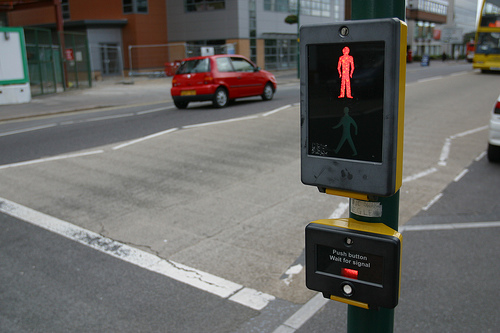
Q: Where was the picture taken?
A: It was taken at the pavement.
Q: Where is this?
A: This is at the pavement.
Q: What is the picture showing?
A: It is showing a pavement.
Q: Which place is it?
A: It is a pavement.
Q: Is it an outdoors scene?
A: Yes, it is outdoors.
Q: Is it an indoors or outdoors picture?
A: It is outdoors.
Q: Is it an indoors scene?
A: No, it is outdoors.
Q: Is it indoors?
A: No, it is outdoors.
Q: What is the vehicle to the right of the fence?
A: The vehicle is a car.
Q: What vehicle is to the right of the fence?
A: The vehicle is a car.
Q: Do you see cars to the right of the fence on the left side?
A: Yes, there is a car to the right of the fence.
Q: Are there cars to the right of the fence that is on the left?
A: Yes, there is a car to the right of the fence.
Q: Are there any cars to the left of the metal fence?
A: No, the car is to the right of the fence.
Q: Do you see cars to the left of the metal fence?
A: No, the car is to the right of the fence.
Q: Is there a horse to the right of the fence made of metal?
A: No, there is a car to the right of the fence.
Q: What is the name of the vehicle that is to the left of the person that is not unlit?
A: The vehicle is a car.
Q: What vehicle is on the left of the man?
A: The vehicle is a car.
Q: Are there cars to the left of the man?
A: Yes, there is a car to the left of the man.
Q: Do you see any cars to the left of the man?
A: Yes, there is a car to the left of the man.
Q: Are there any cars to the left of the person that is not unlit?
A: Yes, there is a car to the left of the man.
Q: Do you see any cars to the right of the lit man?
A: No, the car is to the left of the man.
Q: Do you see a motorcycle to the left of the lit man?
A: No, there is a car to the left of the man.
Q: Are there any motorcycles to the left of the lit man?
A: No, there is a car to the left of the man.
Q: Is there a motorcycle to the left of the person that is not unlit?
A: No, there is a car to the left of the man.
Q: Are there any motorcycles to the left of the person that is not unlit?
A: No, there is a car to the left of the man.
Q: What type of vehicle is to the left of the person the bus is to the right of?
A: The vehicle is a car.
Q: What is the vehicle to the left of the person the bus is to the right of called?
A: The vehicle is a car.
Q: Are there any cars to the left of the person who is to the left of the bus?
A: Yes, there is a car to the left of the person.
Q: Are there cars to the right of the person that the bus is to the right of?
A: No, the car is to the left of the person.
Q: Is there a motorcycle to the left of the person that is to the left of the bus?
A: No, there is a car to the left of the person.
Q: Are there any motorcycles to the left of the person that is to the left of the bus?
A: No, there is a car to the left of the person.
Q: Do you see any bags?
A: No, there are no bags.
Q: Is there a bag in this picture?
A: No, there are no bags.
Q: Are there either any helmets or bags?
A: No, there are no bags or helmets.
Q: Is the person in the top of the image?
A: Yes, the person is in the top of the image.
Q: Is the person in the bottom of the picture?
A: No, the person is in the top of the image.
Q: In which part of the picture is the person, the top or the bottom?
A: The person is in the top of the image.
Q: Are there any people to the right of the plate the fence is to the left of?
A: Yes, there is a person to the right of the plate.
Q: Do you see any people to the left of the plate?
A: No, the person is to the right of the plate.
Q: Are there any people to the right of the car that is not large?
A: Yes, there is a person to the right of the car.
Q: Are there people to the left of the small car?
A: No, the person is to the right of the car.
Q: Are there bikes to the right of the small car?
A: No, there is a person to the right of the car.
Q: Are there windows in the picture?
A: Yes, there are windows.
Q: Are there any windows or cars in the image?
A: Yes, there are windows.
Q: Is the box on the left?
A: No, the box is on the right of the image.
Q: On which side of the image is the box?
A: The box is on the right of the image.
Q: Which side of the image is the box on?
A: The box is on the right of the image.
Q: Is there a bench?
A: No, there are no benches.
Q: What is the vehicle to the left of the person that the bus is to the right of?
A: The vehicle is a car.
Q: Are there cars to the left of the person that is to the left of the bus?
A: Yes, there is a car to the left of the person.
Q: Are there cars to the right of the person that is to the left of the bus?
A: No, the car is to the left of the person.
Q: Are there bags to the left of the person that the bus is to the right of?
A: No, there is a car to the left of the person.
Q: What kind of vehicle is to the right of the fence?
A: The vehicle is a car.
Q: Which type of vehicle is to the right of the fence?
A: The vehicle is a car.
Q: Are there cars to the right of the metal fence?
A: Yes, there is a car to the right of the fence.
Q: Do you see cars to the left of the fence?
A: No, the car is to the right of the fence.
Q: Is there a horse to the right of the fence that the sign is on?
A: No, there is a car to the right of the fence.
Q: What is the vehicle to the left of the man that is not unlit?
A: The vehicle is a car.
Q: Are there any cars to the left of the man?
A: Yes, there is a car to the left of the man.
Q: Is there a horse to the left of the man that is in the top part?
A: No, there is a car to the left of the man.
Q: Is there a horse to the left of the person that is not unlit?
A: No, there is a car to the left of the man.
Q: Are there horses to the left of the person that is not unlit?
A: No, there is a car to the left of the man.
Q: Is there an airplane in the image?
A: No, there are no airplanes.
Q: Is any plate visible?
A: Yes, there is a plate.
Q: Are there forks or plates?
A: Yes, there is a plate.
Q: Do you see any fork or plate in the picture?
A: Yes, there is a plate.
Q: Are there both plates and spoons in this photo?
A: No, there is a plate but no spoons.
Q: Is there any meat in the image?
A: No, there is no meat.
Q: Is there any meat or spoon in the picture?
A: No, there are no meat or spoons.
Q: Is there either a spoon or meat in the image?
A: No, there are no meat or spoons.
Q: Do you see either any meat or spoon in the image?
A: No, there are no meat or spoons.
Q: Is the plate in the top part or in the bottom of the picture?
A: The plate is in the top of the image.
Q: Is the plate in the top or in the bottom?
A: The plate is in the top of the image.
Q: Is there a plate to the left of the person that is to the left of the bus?
A: Yes, there is a plate to the left of the person.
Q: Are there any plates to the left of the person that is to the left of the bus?
A: Yes, there is a plate to the left of the person.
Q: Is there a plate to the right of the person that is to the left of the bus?
A: No, the plate is to the left of the person.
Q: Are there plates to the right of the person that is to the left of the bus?
A: No, the plate is to the left of the person.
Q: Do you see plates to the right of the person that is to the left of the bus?
A: No, the plate is to the left of the person.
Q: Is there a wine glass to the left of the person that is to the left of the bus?
A: No, there is a plate to the left of the person.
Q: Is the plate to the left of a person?
A: Yes, the plate is to the left of a person.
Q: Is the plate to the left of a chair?
A: No, the plate is to the left of a person.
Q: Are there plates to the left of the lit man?
A: Yes, there is a plate to the left of the man.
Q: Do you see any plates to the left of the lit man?
A: Yes, there is a plate to the left of the man.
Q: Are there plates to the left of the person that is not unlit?
A: Yes, there is a plate to the left of the man.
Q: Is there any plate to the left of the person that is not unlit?
A: Yes, there is a plate to the left of the man.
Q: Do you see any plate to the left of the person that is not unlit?
A: Yes, there is a plate to the left of the man.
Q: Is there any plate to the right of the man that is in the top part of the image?
A: No, the plate is to the left of the man.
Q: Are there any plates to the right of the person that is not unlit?
A: No, the plate is to the left of the man.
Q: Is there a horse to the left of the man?
A: No, there is a plate to the left of the man.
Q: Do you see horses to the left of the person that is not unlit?
A: No, there is a plate to the left of the man.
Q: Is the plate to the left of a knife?
A: No, the plate is to the left of the man.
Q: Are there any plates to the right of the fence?
A: Yes, there is a plate to the right of the fence.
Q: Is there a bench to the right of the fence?
A: No, there is a plate to the right of the fence.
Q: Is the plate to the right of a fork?
A: No, the plate is to the right of a fence.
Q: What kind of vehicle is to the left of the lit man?
A: The vehicle is a car.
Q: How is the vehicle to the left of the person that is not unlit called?
A: The vehicle is a car.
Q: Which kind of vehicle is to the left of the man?
A: The vehicle is a car.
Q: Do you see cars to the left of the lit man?
A: Yes, there is a car to the left of the man.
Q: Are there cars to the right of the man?
A: No, the car is to the left of the man.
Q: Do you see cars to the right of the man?
A: No, the car is to the left of the man.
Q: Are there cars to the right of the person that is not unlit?
A: No, the car is to the left of the man.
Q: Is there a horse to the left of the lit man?
A: No, there is a car to the left of the man.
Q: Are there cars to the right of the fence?
A: Yes, there is a car to the right of the fence.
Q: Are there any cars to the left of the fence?
A: No, the car is to the right of the fence.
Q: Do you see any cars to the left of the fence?
A: No, the car is to the right of the fence.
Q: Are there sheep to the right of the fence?
A: No, there is a car to the right of the fence.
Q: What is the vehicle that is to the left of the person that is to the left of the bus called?
A: The vehicle is a car.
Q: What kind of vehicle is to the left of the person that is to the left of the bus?
A: The vehicle is a car.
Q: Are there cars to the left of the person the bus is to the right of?
A: Yes, there is a car to the left of the person.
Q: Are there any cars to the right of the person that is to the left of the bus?
A: No, the car is to the left of the person.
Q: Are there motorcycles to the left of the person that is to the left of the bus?
A: No, there is a car to the left of the person.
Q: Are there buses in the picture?
A: Yes, there is a bus.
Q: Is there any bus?
A: Yes, there is a bus.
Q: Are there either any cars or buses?
A: Yes, there is a bus.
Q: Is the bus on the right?
A: Yes, the bus is on the right of the image.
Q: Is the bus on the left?
A: No, the bus is on the right of the image.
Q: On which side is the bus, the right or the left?
A: The bus is on the right of the image.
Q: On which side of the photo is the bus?
A: The bus is on the right of the image.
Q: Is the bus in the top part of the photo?
A: Yes, the bus is in the top of the image.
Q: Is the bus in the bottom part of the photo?
A: No, the bus is in the top of the image.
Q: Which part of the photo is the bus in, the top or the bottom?
A: The bus is in the top of the image.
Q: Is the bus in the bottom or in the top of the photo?
A: The bus is in the top of the image.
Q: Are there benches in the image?
A: No, there are no benches.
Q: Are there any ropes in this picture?
A: No, there are no ropes.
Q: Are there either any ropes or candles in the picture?
A: No, there are no ropes or candles.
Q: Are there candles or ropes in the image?
A: No, there are no ropes or candles.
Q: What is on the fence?
A: The sign is on the fence.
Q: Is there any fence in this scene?
A: Yes, there is a fence.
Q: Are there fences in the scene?
A: Yes, there is a fence.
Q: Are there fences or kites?
A: Yes, there is a fence.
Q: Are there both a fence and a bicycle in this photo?
A: No, there is a fence but no bicycles.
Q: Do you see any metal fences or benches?
A: Yes, there is a metal fence.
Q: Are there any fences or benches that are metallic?
A: Yes, the fence is metallic.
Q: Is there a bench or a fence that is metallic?
A: Yes, the fence is metallic.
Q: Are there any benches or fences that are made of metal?
A: Yes, the fence is made of metal.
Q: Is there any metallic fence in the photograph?
A: Yes, there is a metal fence.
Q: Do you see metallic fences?
A: Yes, there is a metal fence.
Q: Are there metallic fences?
A: Yes, there is a metal fence.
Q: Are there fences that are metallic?
A: Yes, there is a fence that is metallic.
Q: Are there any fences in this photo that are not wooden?
A: Yes, there is a metallic fence.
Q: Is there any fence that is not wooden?
A: Yes, there is a metallic fence.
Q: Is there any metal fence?
A: Yes, there is a fence that is made of metal.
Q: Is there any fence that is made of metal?
A: Yes, there is a fence that is made of metal.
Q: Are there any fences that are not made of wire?
A: Yes, there is a fence that is made of metal.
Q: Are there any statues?
A: No, there are no statues.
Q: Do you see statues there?
A: No, there are no statues.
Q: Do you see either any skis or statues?
A: No, there are no statues or skis.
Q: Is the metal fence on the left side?
A: Yes, the fence is on the left of the image.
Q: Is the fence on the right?
A: No, the fence is on the left of the image.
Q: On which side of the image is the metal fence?
A: The fence is on the left of the image.